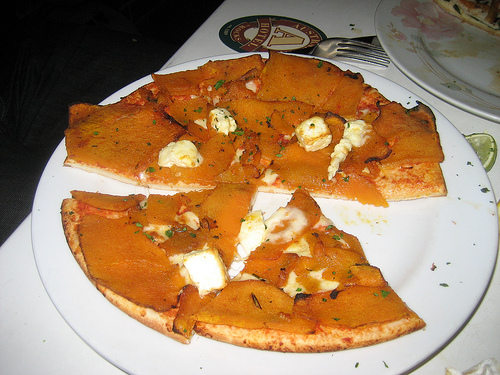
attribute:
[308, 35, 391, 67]
fork — silver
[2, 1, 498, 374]
table — white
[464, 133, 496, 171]
lime — cut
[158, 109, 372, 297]
topping — white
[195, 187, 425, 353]
pizza slice — slice of, lox, slices of, ceese, triangular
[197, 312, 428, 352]
crust — cooked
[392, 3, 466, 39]
flower — pink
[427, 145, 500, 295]
flakes — green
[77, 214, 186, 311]
topping — orange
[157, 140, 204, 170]
cheese — white, melted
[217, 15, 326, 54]
logo — hotel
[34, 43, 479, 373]
plate — white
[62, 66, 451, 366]
pizza — cooked